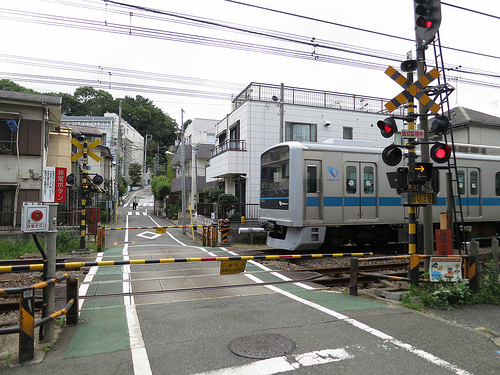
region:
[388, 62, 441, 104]
yellow and gray railroad crossing sign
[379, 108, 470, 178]
flashing lights at railroad crossing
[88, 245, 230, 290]
barrier at railroad crossing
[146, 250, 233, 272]
barrier is yellow and black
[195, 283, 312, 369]
manhole in asphalt road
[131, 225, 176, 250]
large white diamond on asphalt road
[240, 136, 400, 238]
front of gray train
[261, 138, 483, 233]
train has many windows and doors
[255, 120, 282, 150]
white building behind train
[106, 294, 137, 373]
white line on asphalt road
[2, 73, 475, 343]
a train is crossing and red lights and rail is down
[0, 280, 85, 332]
yellow and black railing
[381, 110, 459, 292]
a red light train signal is on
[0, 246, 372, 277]
a train crossing bar is down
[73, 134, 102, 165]
a yellow train crossing sign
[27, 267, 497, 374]
a road with white lines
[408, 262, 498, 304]
some weeds are on the side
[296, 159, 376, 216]
doors to train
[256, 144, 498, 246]
a white and blue train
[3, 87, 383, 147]
white buildings in background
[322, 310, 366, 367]
A white line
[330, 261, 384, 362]
A white line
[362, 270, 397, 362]
A white line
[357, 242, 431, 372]
A white line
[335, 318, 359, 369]
A white line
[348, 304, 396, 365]
A white line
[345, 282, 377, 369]
A white line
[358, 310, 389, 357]
A white line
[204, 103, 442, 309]
the train is white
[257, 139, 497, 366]
the train is white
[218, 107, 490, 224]
a train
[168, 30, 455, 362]
a train